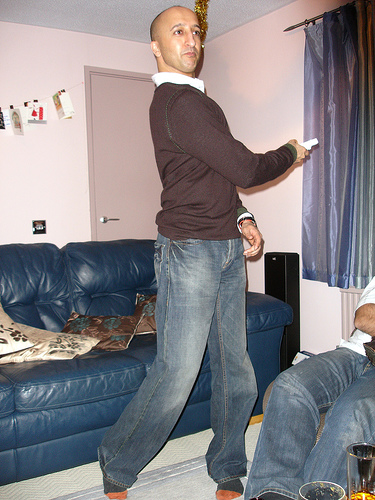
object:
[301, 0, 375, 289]
curtain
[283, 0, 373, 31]
rod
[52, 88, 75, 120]
card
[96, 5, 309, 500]
man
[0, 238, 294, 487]
couch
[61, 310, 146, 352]
pillow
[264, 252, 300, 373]
speaker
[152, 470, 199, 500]
floor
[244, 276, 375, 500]
man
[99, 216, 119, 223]
handle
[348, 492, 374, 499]
liquid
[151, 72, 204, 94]
collar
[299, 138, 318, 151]
remote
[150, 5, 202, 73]
head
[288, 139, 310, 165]
hand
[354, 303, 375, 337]
elbow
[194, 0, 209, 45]
garland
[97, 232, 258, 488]
jean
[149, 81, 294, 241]
shirt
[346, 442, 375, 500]
cup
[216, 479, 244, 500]
sock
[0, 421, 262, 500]
rug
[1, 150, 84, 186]
wall